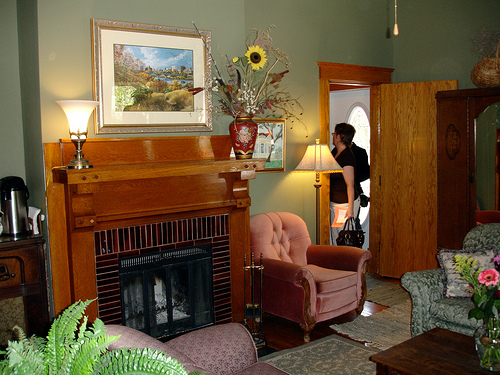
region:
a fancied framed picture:
[90, 17, 212, 132]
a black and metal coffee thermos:
[0, 173, 32, 238]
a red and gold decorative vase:
[228, 108, 256, 159]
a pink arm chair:
[246, 210, 371, 342]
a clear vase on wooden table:
[473, 314, 498, 373]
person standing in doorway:
[332, 121, 366, 247]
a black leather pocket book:
[336, 218, 364, 247]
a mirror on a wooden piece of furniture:
[467, 95, 499, 224]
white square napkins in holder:
[27, 205, 42, 235]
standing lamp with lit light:
[296, 138, 343, 245]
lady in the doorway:
[313, 111, 373, 184]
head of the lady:
[320, 120, 357, 157]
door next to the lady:
[361, 74, 445, 159]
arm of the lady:
[336, 160, 368, 230]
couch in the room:
[242, 203, 359, 325]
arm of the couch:
[302, 228, 376, 277]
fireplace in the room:
[92, 177, 247, 338]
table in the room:
[363, 309, 474, 374]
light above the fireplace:
[44, 88, 114, 179]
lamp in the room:
[279, 130, 343, 222]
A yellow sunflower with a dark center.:
[241, 42, 271, 74]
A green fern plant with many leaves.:
[1, 290, 188, 374]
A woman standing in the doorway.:
[325, 115, 370, 242]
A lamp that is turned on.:
[47, 88, 111, 173]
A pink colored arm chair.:
[248, 206, 377, 344]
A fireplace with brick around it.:
[89, 208, 239, 342]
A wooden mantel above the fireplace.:
[47, 150, 270, 192]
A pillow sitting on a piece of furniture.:
[433, 244, 497, 300]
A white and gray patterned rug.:
[260, 330, 384, 372]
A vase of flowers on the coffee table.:
[448, 248, 498, 374]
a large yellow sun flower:
[243, 43, 270, 73]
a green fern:
[1, 294, 188, 374]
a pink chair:
[251, 209, 373, 339]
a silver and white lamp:
[54, 96, 100, 168]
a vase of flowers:
[451, 255, 498, 371]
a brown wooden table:
[368, 326, 498, 373]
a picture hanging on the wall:
[89, 24, 211, 131]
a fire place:
[44, 137, 254, 342]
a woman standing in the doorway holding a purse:
[328, 119, 369, 246]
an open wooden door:
[321, 65, 458, 278]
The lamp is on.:
[51, 92, 108, 182]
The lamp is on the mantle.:
[42, 87, 108, 183]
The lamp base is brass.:
[62, 125, 102, 182]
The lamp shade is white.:
[47, 84, 96, 154]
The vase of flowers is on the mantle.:
[196, 20, 282, 176]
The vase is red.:
[221, 107, 260, 163]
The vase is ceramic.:
[223, 109, 259, 161]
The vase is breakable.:
[221, 111, 263, 174]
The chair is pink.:
[248, 196, 370, 336]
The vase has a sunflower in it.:
[202, 19, 274, 164]